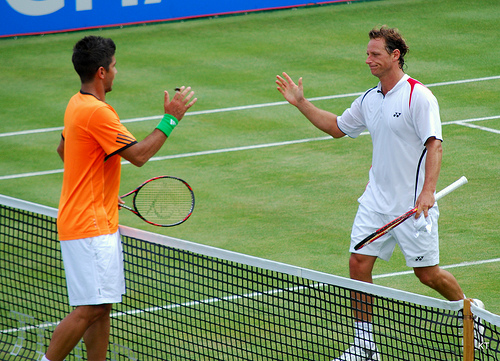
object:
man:
[40, 34, 198, 361]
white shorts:
[59, 228, 126, 307]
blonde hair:
[367, 23, 409, 72]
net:
[0, 196, 499, 361]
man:
[274, 22, 484, 360]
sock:
[354, 321, 374, 354]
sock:
[455, 295, 473, 325]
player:
[37, 33, 199, 360]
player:
[276, 25, 485, 360]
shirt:
[337, 73, 474, 217]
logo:
[415, 256, 423, 261]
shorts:
[349, 202, 440, 267]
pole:
[462, 299, 474, 361]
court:
[0, 2, 498, 354]